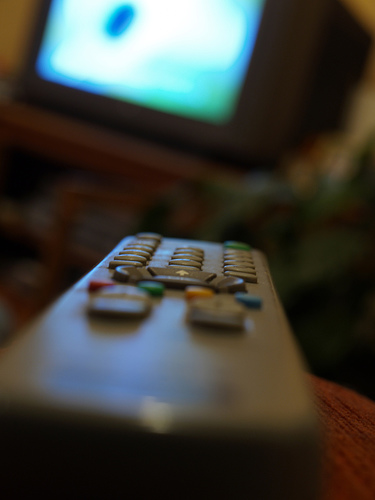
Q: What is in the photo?
A: A remote.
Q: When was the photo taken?
A: Nighttime.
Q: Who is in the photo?
A: Nobody.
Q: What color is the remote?
A: Black.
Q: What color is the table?
A: Brown.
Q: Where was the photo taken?
A: In a TV room.